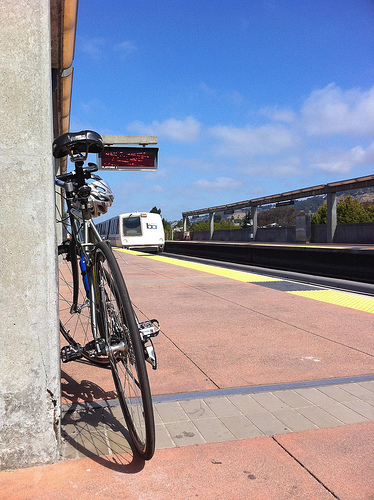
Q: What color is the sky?
A: Blue.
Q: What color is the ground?
A: Red and gray.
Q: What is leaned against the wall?
A: Bike.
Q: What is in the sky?
A: Clouds.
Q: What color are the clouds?
A: White.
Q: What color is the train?
A: White.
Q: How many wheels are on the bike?
A: Two.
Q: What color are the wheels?
A: Black.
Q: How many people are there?
A: None.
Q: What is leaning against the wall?
A: Bike.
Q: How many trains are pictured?
A: 1.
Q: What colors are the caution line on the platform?
A: Black and yellow.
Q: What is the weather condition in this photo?
A: Clear and sunny.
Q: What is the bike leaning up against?
A: Concrete wall.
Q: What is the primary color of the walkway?
A: Red.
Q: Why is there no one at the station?
A: Too early.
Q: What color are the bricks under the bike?
A: Grey.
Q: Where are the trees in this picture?
A: Behind the station wall.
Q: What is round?
A: Wheels.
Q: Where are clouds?
A: In the sky.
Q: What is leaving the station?
A: Train.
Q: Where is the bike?
A: Beside the wall.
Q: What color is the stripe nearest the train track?
A: Yellow.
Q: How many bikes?
A: One.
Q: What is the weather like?
A: Sunny.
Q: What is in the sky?
A: Clouds.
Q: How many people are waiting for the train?
A: None.